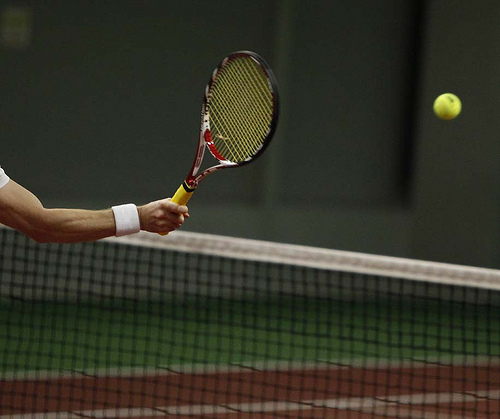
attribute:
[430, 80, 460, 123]
ball — yellow, tennis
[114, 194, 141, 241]
wristband — white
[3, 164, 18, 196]
sleeve — white, shirt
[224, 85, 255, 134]
strings — yellow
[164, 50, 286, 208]
racket — tennis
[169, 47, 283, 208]
tennis racket — black, red, yellow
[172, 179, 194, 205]
handle — yellow